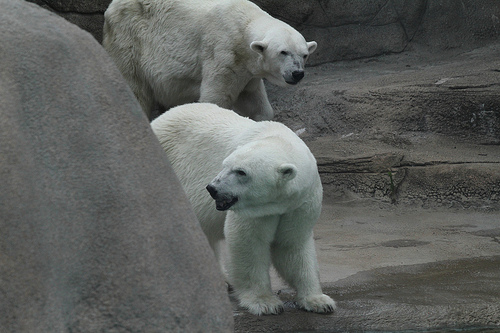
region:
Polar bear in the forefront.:
[147, 99, 345, 321]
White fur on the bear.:
[147, 98, 337, 323]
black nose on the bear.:
[200, 178, 222, 200]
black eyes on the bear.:
[273, 45, 309, 63]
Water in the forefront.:
[233, 248, 497, 332]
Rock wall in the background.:
[41, 0, 494, 78]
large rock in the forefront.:
[0, 0, 246, 332]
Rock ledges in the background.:
[293, 40, 495, 208]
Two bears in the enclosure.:
[98, 0, 340, 318]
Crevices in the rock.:
[288, 0, 425, 75]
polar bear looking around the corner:
[142, 101, 338, 331]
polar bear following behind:
[102, 3, 294, 106]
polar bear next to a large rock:
[120, 86, 341, 320]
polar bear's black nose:
[205, 181, 223, 202]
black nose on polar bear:
[291, 63, 303, 85]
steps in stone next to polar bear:
[307, 74, 498, 239]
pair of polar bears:
[100, 3, 353, 327]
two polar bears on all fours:
[93, 1, 340, 320]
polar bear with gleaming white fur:
[144, 103, 344, 320]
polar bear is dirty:
[92, 1, 306, 133]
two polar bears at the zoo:
[89, 6, 364, 327]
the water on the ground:
[230, 255, 498, 330]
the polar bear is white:
[141, 97, 353, 323]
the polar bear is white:
[97, 0, 351, 107]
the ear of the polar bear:
[234, 30, 270, 57]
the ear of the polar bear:
[294, 38, 323, 53]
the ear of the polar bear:
[275, 155, 305, 190]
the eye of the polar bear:
[227, 166, 251, 178]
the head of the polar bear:
[192, 145, 298, 215]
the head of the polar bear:
[237, 21, 322, 86]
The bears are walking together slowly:
[20, 6, 455, 316]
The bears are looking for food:
[35, 20, 450, 330]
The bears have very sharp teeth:
[47, 8, 472, 328]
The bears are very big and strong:
[61, 15, 461, 331]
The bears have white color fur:
[58, 5, 424, 330]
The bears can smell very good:
[51, 8, 452, 329]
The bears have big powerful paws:
[26, 20, 482, 330]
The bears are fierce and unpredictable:
[30, 5, 453, 315]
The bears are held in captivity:
[11, 8, 496, 319]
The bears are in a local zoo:
[25, 14, 498, 317]